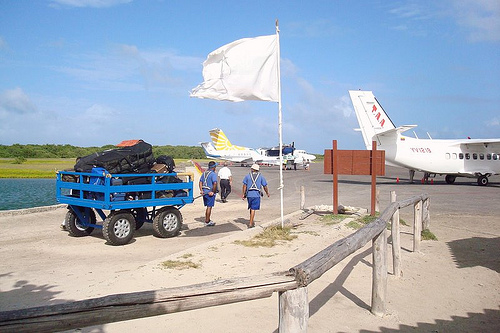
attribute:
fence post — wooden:
[351, 223, 398, 325]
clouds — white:
[2, 84, 116, 139]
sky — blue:
[2, 2, 196, 138]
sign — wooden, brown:
[323, 142, 389, 210]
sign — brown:
[318, 138, 394, 218]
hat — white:
[250, 160, 263, 171]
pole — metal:
[274, 12, 284, 230]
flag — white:
[189, 33, 285, 103]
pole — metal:
[274, 101, 289, 227]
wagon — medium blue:
[72, 152, 173, 212]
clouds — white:
[388, 10, 496, 83]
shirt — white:
[211, 144, 248, 184]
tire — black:
[101, 212, 135, 244]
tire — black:
[64, 204, 96, 236]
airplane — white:
[346, 87, 499, 188]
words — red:
[366, 101, 389, 131]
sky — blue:
[366, 8, 462, 65]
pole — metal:
[275, 15, 284, 227]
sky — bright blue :
[39, 26, 446, 147]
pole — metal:
[265, 15, 294, 232]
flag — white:
[186, 28, 286, 111]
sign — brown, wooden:
[321, 137, 388, 217]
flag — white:
[190, 16, 327, 138]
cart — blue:
[51, 162, 193, 246]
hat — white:
[250, 162, 260, 171]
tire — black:
[150, 205, 182, 237]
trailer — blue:
[56, 170, 193, 245]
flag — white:
[177, 34, 322, 114]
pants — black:
[217, 181, 231, 205]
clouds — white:
[11, 42, 175, 134]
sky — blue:
[24, 19, 158, 83]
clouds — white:
[16, 50, 154, 117]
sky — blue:
[4, 4, 483, 123]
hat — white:
[250, 163, 260, 174]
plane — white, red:
[343, 84, 498, 187]